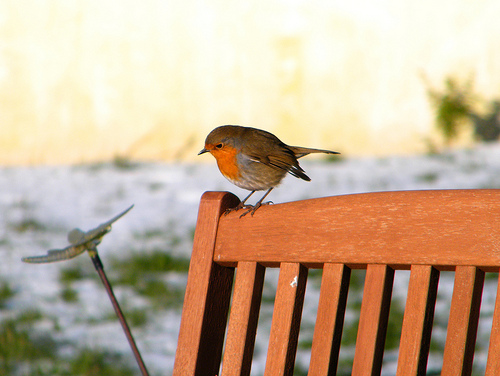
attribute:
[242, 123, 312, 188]
birds wing — brown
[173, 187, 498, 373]
bench — wooden, brown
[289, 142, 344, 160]
tail feather — brown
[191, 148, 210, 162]
beak — black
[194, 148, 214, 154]
bird beak — short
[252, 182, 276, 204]
leg — thin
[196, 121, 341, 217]
bird — brown, orange, small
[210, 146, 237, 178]
chest — orange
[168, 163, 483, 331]
bench — wooden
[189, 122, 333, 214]
bird — small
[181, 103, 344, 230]
bird — small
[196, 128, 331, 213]
bird — small